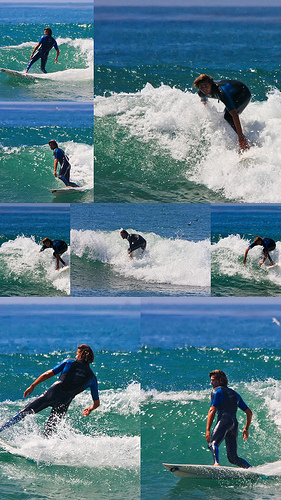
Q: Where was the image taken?
A: It was taken at the ocean.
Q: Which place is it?
A: It is an ocean.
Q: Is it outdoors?
A: Yes, it is outdoors.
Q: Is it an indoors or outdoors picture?
A: It is outdoors.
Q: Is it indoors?
A: No, it is outdoors.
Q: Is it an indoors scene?
A: No, it is outdoors.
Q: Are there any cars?
A: No, there are no cars.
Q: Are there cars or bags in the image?
A: No, there are no cars or bags.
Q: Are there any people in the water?
A: Yes, there is a person in the water.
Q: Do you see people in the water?
A: Yes, there is a person in the water.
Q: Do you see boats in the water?
A: No, there is a person in the water.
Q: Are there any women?
A: Yes, there is a woman.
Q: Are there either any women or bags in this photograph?
A: Yes, there is a woman.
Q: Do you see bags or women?
A: Yes, there is a woman.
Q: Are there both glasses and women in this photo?
A: No, there is a woman but no glasses.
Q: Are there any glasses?
A: No, there are no glasses.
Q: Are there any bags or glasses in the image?
A: No, there are no glasses or bags.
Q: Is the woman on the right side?
A: Yes, the woman is on the right of the image.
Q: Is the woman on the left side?
A: No, the woman is on the right of the image.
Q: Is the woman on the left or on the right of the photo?
A: The woman is on the right of the image.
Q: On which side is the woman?
A: The woman is on the right of the image.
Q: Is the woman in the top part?
A: Yes, the woman is in the top of the image.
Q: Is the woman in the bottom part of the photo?
A: No, the woman is in the top of the image.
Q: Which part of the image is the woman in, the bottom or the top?
A: The woman is in the top of the image.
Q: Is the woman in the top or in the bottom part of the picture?
A: The woman is in the top of the image.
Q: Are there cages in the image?
A: No, there are no cages.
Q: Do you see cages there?
A: No, there are no cages.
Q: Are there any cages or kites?
A: No, there are no cages or kites.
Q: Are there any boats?
A: No, there are no boats.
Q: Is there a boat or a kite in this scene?
A: No, there are no boats or kites.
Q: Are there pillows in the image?
A: No, there are no pillows.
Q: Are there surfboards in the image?
A: Yes, there is a surfboard.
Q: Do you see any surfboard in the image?
A: Yes, there is a surfboard.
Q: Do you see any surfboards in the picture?
A: Yes, there is a surfboard.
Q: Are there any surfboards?
A: Yes, there is a surfboard.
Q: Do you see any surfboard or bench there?
A: Yes, there is a surfboard.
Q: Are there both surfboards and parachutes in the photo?
A: No, there is a surfboard but no parachutes.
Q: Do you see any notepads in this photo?
A: No, there are no notepads.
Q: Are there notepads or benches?
A: No, there are no notepads or benches.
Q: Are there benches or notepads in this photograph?
A: No, there are no notepads or benches.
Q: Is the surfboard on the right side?
A: Yes, the surfboard is on the right of the image.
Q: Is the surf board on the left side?
A: No, the surf board is on the right of the image.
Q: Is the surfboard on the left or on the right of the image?
A: The surfboard is on the right of the image.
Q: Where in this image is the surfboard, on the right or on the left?
A: The surfboard is on the right of the image.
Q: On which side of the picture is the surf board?
A: The surf board is on the right of the image.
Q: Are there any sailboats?
A: No, there are no sailboats.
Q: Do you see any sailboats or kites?
A: No, there are no sailboats or kites.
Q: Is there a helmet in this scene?
A: No, there are no helmets.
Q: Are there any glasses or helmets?
A: No, there are no helmets or glasses.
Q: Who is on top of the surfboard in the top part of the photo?
A: The man is on top of the surfboard.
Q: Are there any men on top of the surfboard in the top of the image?
A: Yes, there is a man on top of the surfboard.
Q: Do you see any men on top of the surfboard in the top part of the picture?
A: Yes, there is a man on top of the surfboard.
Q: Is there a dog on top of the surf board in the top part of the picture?
A: No, there is a man on top of the surfboard.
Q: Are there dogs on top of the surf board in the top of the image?
A: No, there is a man on top of the surfboard.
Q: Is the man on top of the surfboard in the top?
A: Yes, the man is on top of the surfboard.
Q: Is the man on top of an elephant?
A: No, the man is on top of the surfboard.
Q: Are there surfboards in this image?
A: Yes, there is a surfboard.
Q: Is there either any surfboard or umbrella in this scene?
A: Yes, there is a surfboard.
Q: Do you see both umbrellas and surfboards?
A: No, there is a surfboard but no umbrellas.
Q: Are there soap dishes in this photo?
A: No, there are no soap dishes.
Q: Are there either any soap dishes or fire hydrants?
A: No, there are no soap dishes or fire hydrants.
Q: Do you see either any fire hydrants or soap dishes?
A: No, there are no soap dishes or fire hydrants.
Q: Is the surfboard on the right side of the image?
A: Yes, the surfboard is on the right of the image.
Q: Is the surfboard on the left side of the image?
A: No, the surfboard is on the right of the image.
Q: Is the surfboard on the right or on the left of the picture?
A: The surfboard is on the right of the image.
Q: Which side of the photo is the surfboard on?
A: The surfboard is on the right of the image.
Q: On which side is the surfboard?
A: The surfboard is on the right of the image.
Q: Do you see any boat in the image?
A: No, there are no boats.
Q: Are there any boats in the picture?
A: No, there are no boats.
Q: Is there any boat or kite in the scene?
A: No, there are no boats or kites.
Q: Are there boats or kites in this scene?
A: No, there are no boats or kites.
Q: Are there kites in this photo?
A: No, there are no kites.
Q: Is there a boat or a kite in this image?
A: No, there are no kites or boats.